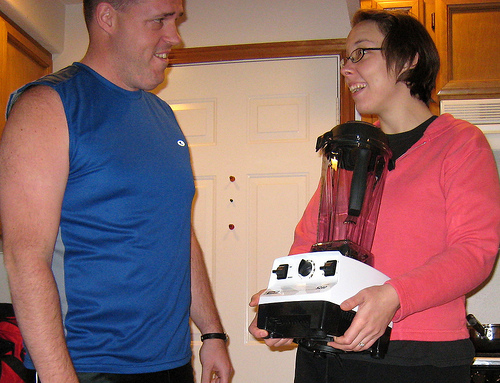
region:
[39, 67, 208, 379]
man wears blue shirt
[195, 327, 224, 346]
man wears watch on left hand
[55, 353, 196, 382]
man wears black pants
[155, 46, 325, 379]
door is white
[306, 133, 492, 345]
woman wears red sweater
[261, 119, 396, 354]
woman is holding electric blender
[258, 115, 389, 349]
electric blender is black and white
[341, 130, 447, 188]
woman wears black shirt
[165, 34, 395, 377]
white door has wooden frame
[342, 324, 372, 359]
woman wears ring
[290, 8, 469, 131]
Woman is wearing eye glasses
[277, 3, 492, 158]
Woman has short brown hair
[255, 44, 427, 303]
Woman is holding a blender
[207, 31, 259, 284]
White door with peep hole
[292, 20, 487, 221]
Woman is wearing a pink sweat shirt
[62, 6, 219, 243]
Man is wearing a blue shirt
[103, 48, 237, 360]
Man is wearing a black watch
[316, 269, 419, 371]
Woman is wearing a wedding ring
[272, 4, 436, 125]
The woman is smiling and happy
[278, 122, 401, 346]
Blender is white with black base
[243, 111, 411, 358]
blender with white base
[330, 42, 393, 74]
pair of black eyeglasses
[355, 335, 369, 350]
ring on a finger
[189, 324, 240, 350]
watch on a wrist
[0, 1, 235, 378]
person in a blue shirt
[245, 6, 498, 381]
person in a pink shirt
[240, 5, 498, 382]
person holding a blender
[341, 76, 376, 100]
an open mouth on a woman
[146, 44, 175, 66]
open mouth on a man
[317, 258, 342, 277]
knob on a blender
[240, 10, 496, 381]
Woman holding kitchen appliance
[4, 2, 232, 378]
Man wearing a muscle shirt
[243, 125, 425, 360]
Black and white kitchen appliance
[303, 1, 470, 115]
Woman wearing glasses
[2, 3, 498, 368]
Two people standing in a kitchen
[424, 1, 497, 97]
Wood kitchen cabinets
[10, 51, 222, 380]
Blue and grey muscle shirt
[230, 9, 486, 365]
Woman in pink shirt holding a blender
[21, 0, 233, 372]
Man staring at woman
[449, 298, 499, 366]
Black and silver pot on stove top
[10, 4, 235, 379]
man standing next to woman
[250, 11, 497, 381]
woman holding a blender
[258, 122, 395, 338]
black and white blender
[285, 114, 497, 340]
pink sweater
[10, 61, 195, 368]
blue tank top with gray trim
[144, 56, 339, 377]
white door behind the people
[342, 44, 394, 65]
eyeglasses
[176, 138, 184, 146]
C9 logo on tank top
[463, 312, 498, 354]
saucepan on stove behind woman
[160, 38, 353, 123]
wooden trim around door